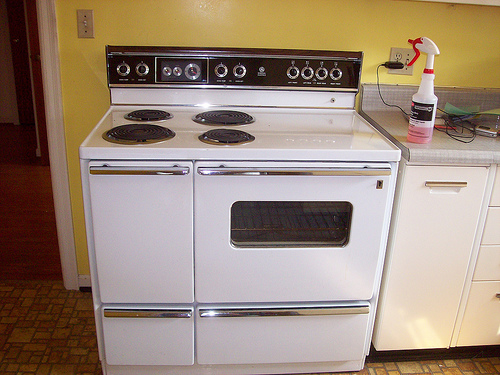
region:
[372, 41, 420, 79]
Black plug in an electric outlet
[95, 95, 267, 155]
Four burners on a stove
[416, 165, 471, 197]
A handle on a cabinet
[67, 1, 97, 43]
Light switch on the wall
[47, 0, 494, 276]
A yellow colored wall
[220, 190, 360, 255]
A window on the oven door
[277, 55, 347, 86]
Four knobs on a stove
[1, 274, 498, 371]
Mosaic tiles on the floor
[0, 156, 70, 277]
A floor is wooden and brown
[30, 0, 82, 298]
A doorway is white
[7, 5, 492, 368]
Picture taken in the kitchen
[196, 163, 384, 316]
This is the oven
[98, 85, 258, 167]
This is the stove top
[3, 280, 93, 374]
The floor is tiled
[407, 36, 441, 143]
A bottle of cleaning product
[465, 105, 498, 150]
A cell phone on the counter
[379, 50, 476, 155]
A phone charger plugged into the wall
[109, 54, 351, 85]
Buttons to operate the oven and stove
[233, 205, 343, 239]
Oven rack inside of the oven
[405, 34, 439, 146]
bottle of cleaning solution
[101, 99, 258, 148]
stove top burners on top of the oven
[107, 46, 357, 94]
knobs on the oven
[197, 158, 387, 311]
oven door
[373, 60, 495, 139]
cell phone is plugged into an outlet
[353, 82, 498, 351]
counter with white cabinets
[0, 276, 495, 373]
multicolor brown tile on the ground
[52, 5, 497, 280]
back wall of the kitchen is yellow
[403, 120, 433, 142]
dark pink cleaning solution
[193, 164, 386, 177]
metal handle on the oven door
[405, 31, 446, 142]
a red and white spray bottle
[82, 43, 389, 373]
a large black and white oven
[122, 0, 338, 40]
part of a painted yellow wall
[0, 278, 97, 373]
part of a tile floor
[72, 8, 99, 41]
a beige light switch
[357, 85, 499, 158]
part of a gray counter top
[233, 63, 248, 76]
a black and gray oven knob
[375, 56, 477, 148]
a long black cord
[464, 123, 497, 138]
a gray cellphone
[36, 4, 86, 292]
a long white door trim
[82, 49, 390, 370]
the oven is white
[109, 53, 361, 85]
the oven has many knobs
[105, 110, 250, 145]
the stove has four burners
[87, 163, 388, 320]
the handles are silver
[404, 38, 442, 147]
the spray bottle has liquid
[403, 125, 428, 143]
the liquid is pink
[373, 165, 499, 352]
the cabinet is white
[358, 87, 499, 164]
the counter top is gray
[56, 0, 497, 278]
the wall is yellow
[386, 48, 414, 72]
the outlet is beige